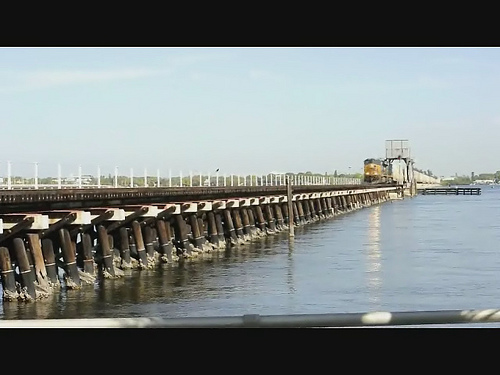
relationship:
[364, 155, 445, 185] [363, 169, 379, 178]
train has headlights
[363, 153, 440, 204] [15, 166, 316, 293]
train on bridge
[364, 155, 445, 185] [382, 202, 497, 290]
train near water